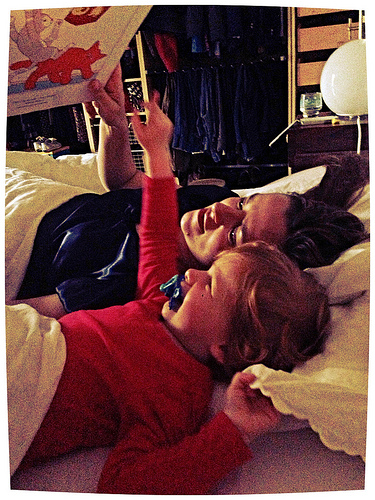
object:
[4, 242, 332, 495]
child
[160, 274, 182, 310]
pacifier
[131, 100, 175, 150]
hand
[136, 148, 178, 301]
arm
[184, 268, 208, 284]
nose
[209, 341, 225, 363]
ear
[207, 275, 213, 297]
eye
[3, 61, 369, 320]
woman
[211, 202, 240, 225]
nose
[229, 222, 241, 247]
eye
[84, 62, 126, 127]
hand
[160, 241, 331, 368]
head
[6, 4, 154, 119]
book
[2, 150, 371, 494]
bed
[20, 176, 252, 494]
shirt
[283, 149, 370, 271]
hair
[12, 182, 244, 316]
top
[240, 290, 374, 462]
pillow case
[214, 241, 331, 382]
hair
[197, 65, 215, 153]
jeans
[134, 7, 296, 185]
closet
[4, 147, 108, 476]
blanket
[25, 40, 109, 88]
character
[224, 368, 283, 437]
hand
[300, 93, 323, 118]
glass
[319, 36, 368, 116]
lamp shade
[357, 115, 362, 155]
base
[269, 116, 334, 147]
controller